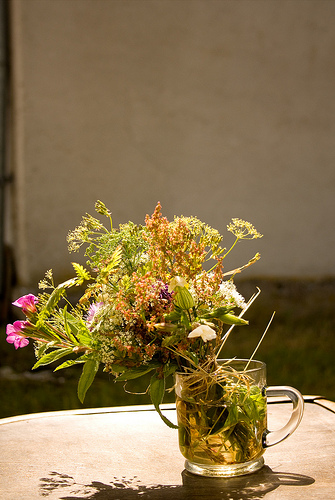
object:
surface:
[2, 396, 334, 500]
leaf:
[218, 309, 251, 327]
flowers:
[6, 193, 265, 429]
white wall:
[47, 470, 176, 498]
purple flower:
[4, 291, 39, 349]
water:
[177, 392, 267, 462]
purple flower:
[82, 299, 104, 328]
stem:
[182, 395, 268, 461]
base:
[183, 458, 265, 478]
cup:
[174, 359, 303, 478]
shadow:
[38, 468, 315, 500]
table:
[1, 393, 335, 500]